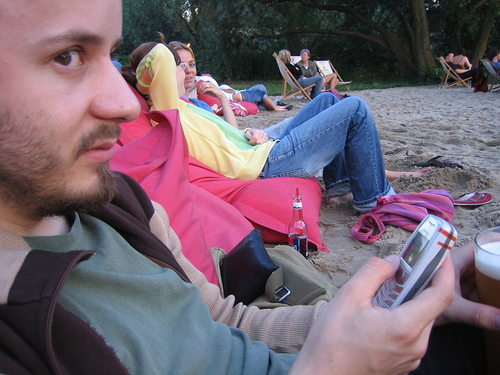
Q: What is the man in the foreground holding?
A: Cell phone.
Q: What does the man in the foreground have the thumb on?
A: Button.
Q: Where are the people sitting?
A: Tan sand.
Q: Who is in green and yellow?
A: A girl.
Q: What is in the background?
A: A line of trees.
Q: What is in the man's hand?
A: A grey and silver cellphone.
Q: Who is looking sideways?
A: The man.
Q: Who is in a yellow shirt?
A: The girl.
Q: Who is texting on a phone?
A: The man.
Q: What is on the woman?
A: A yellow sweater.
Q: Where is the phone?
A: In hand.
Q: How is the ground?
A: Sandy.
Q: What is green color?
A: Forest.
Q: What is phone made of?
A: Plastic.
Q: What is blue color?
A: Jeans.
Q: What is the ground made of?
A: Sand.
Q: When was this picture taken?
A: Daytime.